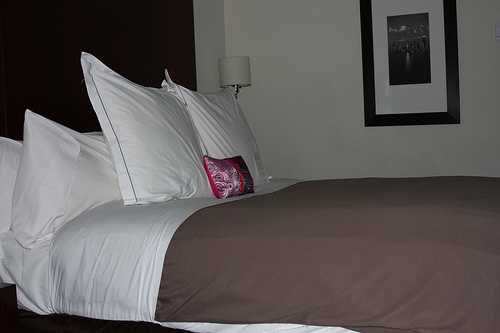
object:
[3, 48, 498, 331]
bed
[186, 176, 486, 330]
comforter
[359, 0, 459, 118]
picture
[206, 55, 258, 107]
lamp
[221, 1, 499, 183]
wall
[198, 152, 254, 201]
pillow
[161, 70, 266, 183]
pillow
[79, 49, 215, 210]
pillow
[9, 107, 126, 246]
pillow